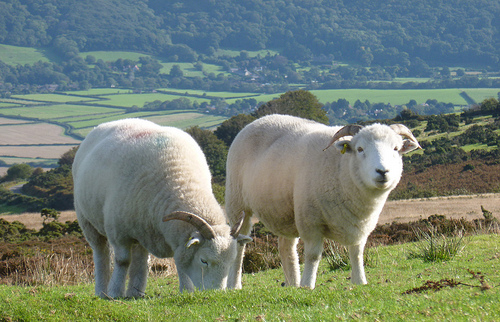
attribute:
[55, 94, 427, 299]
sheep — white, looking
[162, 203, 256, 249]
horns — tan, brown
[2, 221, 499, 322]
grass — tall, green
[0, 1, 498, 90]
trees — far, full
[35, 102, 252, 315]
sheep — eating, looking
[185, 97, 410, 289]
sheep — grazing, looking